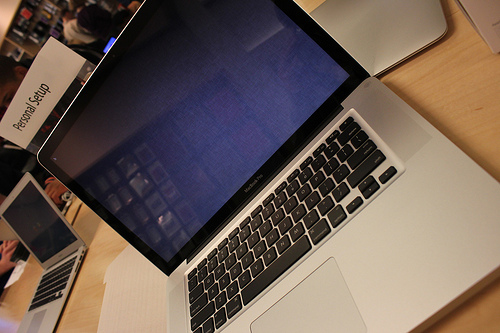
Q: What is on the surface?
A: A laptop.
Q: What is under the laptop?
A: Wood grain surface.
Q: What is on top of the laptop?
A: Keyboard.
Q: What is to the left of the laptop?
A: Another laptop.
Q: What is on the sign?
A: Personal setup.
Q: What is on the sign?
A: Bit of information.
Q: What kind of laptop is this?
A: An Apple Macbook pro.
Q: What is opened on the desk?
A: A laptop computer.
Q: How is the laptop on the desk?
A: THe laptop is opened.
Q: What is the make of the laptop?
A: The laptop is an Apple MacBook Air.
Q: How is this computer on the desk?
A: The is computer is closed.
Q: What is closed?
A: An Apple MacBook.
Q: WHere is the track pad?
A: On the lower part of the computer.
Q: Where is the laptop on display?
A: The laptop is on display on a flat surface.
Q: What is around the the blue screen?
A: A black frame.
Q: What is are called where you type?
A: Keyboard.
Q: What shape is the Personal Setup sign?
A: Rectangle.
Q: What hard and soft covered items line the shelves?
A: Books.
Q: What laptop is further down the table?
A: The more silver one.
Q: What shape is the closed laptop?
A: Rectangle.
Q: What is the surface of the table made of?
A: Wood.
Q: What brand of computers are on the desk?
A: Apple.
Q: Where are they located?
A: A store.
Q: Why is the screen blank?
A: The computer is being set up.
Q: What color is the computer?
A: Silver.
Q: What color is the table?
A: Brown.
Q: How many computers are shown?
A: 3.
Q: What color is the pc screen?
A: Black.